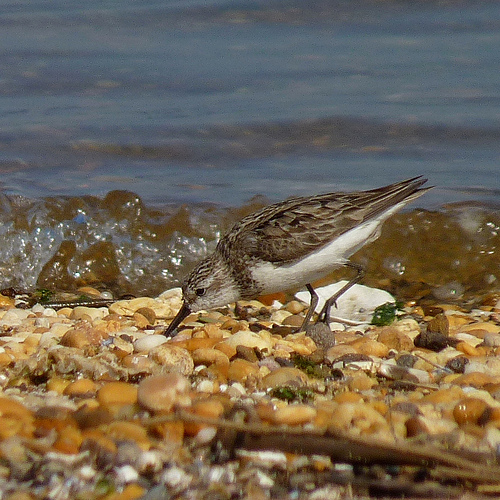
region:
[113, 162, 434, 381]
BIRD HAS WHITE UNDERBELLY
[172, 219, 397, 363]
the bird is grey and white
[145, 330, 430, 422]
the pebbles are brown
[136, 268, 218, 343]
the beak is in the stone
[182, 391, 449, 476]
there are twiggs on the ground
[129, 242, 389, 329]
the bird is searching for food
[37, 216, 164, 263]
there are water droplets in the air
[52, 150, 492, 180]
there is water in the back ground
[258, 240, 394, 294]
the belly is white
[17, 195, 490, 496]
the scene is outdoors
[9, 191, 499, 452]
its a daytime photo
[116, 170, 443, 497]
a bird on the beach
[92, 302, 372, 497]
lots of orange and white pebbles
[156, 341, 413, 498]
twigs lying on pebbles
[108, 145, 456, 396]
bird scavenging for food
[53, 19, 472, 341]
a bird near an ocean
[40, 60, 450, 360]
a wave of water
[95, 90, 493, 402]
one lone bird by itself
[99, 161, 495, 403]
bird looking for food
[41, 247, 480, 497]
bird trying to find food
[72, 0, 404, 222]
calm ocean in the background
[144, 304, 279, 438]
many pebble are on the shore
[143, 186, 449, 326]
the bird is brown & white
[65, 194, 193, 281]
the water is brown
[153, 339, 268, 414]
the pebbles are brown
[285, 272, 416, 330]
a white sea shell is in the background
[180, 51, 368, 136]
the water is gray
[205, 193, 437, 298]
the belly of the bird is white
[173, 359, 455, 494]
a stick is in the foreground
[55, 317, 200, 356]
some of the pebbles are white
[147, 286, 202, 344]
the bird has a long beak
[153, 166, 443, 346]
Bird is brown and white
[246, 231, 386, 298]
Chest of bird is white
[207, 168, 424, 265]
Wings of bird are brown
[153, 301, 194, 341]
Bird has long peak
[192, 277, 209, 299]
Small eye of bird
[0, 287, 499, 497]
Stones are yellow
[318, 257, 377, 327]
Left feet is up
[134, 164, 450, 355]
Bird is drinking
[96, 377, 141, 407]
Yellow stone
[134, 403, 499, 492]
Brown sticks on stones